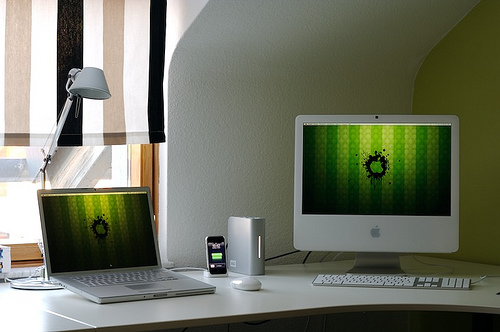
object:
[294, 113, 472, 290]
computer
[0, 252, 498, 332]
desk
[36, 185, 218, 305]
laptop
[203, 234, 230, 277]
cell phone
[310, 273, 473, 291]
keyboard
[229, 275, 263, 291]
mouse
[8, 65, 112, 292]
desk lamp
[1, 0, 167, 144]
curtain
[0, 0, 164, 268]
window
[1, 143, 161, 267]
frame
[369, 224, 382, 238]
logo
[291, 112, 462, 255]
monitor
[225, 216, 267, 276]
hard drive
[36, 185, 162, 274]
monitor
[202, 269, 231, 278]
charger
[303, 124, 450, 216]
green background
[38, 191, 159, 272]
green background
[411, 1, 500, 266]
side wall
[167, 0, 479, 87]
overhang